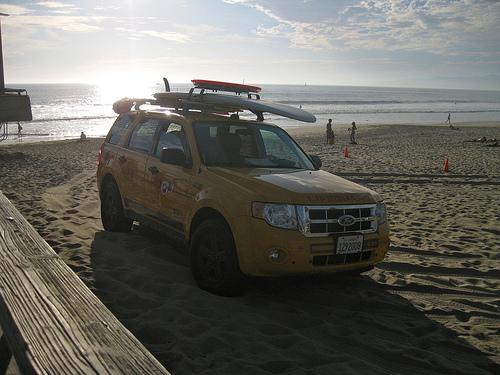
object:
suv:
[92, 103, 394, 294]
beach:
[1, 121, 499, 372]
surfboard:
[154, 86, 320, 120]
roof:
[124, 109, 279, 125]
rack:
[150, 79, 326, 122]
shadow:
[91, 227, 463, 373]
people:
[343, 118, 361, 143]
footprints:
[57, 177, 93, 228]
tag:
[334, 232, 366, 254]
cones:
[348, 145, 442, 170]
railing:
[3, 224, 62, 373]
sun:
[97, 50, 161, 91]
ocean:
[4, 82, 499, 121]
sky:
[0, 3, 499, 89]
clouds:
[337, 3, 496, 53]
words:
[308, 193, 372, 203]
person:
[77, 130, 89, 142]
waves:
[434, 103, 498, 112]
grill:
[310, 206, 377, 229]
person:
[445, 109, 455, 127]